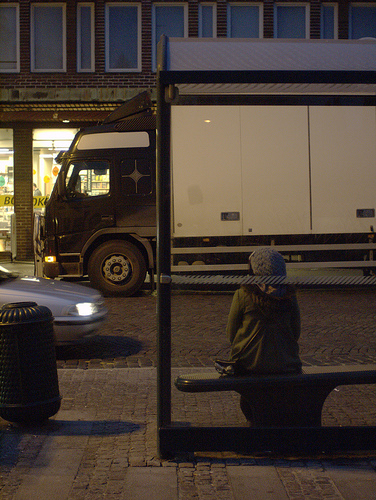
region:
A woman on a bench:
[229, 247, 300, 369]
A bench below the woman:
[175, 364, 374, 425]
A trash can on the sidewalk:
[2, 300, 59, 424]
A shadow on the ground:
[24, 417, 137, 435]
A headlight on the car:
[73, 300, 93, 313]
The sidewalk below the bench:
[0, 367, 374, 499]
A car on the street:
[1, 264, 104, 342]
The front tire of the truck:
[88, 241, 143, 293]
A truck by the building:
[41, 37, 375, 289]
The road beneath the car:
[1, 278, 374, 368]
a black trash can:
[2, 301, 61, 421]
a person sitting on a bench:
[224, 245, 297, 384]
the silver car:
[1, 263, 107, 342]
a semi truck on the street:
[43, 81, 365, 292]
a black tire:
[92, 237, 144, 292]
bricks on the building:
[12, 124, 34, 259]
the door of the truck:
[64, 158, 115, 228]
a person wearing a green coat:
[231, 251, 302, 376]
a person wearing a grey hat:
[243, 248, 285, 303]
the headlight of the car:
[78, 302, 94, 314]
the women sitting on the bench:
[215, 245, 306, 386]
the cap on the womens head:
[247, 245, 289, 284]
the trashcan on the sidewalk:
[1, 302, 71, 437]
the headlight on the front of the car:
[66, 296, 99, 318]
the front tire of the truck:
[88, 240, 142, 297]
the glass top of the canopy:
[159, 35, 374, 95]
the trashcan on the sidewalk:
[4, 416, 143, 433]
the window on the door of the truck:
[63, 155, 114, 200]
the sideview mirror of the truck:
[54, 167, 71, 199]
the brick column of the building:
[11, 124, 36, 253]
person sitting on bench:
[113, 8, 370, 486]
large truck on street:
[26, 42, 371, 298]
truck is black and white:
[4, 68, 374, 290]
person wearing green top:
[208, 282, 315, 376]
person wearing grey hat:
[239, 234, 288, 290]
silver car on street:
[1, 247, 114, 363]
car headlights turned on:
[1, 253, 118, 352]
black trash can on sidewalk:
[3, 282, 96, 443]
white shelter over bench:
[117, 25, 373, 445]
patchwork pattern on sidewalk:
[76, 367, 146, 492]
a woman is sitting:
[182, 223, 312, 408]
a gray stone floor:
[100, 384, 164, 464]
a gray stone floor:
[76, 387, 168, 497]